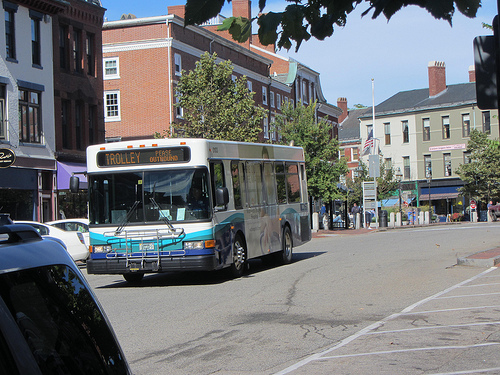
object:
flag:
[359, 129, 373, 157]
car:
[13, 220, 91, 262]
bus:
[70, 138, 312, 282]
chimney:
[427, 60, 448, 99]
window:
[31, 92, 40, 104]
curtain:
[462, 114, 469, 122]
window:
[460, 114, 471, 138]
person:
[318, 203, 327, 222]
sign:
[469, 200, 478, 221]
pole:
[370, 78, 379, 229]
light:
[99, 147, 105, 151]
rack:
[103, 227, 186, 269]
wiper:
[149, 197, 175, 233]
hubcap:
[233, 241, 245, 271]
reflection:
[48, 264, 123, 368]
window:
[0, 262, 132, 375]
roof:
[354, 82, 499, 120]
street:
[0, 223, 499, 375]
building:
[103, 0, 347, 233]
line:
[273, 262, 500, 375]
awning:
[415, 186, 462, 200]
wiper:
[113, 201, 140, 237]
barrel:
[379, 209, 388, 227]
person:
[349, 203, 362, 230]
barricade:
[387, 212, 395, 226]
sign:
[361, 181, 379, 228]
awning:
[56, 161, 109, 185]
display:
[96, 145, 191, 166]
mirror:
[215, 187, 230, 207]